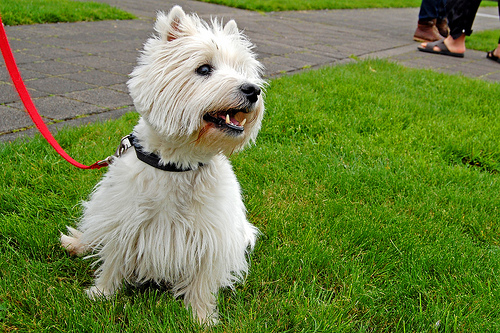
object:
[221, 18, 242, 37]
ear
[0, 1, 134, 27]
grass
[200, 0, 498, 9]
grass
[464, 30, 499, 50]
grass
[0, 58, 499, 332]
grass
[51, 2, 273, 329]
fur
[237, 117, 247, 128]
teeth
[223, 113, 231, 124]
teeth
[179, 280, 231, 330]
paw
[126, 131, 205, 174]
collar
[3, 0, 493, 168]
sidewalk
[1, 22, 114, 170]
leash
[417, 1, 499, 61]
people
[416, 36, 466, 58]
feet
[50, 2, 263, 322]
boat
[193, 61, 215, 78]
eye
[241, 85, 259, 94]
nostril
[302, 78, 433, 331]
ground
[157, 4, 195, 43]
ear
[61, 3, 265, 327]
dog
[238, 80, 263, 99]
nose